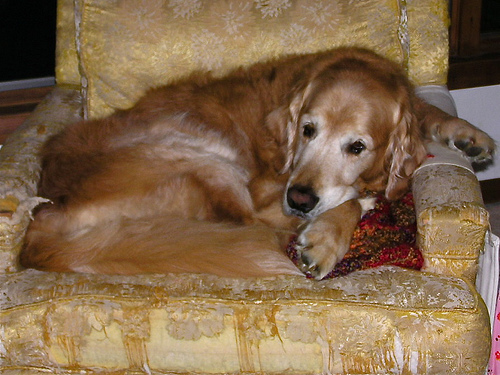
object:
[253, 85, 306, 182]
ear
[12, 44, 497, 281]
dog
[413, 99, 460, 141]
arm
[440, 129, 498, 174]
paw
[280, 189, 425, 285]
blanket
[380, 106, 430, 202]
ear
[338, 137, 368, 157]
eye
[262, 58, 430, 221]
head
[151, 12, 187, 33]
fabric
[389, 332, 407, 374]
tear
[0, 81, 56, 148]
table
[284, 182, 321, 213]
nose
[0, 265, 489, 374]
cushion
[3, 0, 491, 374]
arm chair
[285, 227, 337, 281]
paw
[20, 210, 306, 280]
tail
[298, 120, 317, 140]
eye